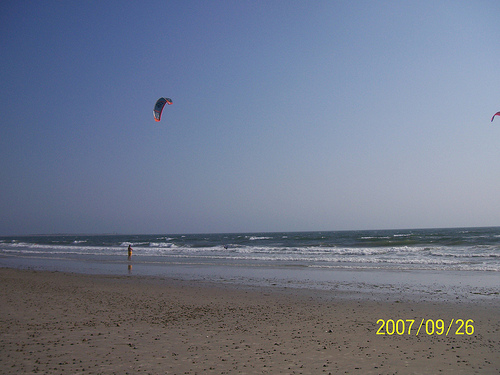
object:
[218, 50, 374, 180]
no clouds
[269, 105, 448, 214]
small tree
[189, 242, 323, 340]
wet sand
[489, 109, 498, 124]
parachute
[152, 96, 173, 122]
kite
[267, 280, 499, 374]
ground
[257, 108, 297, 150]
wall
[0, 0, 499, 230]
blue sky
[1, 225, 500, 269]
ocean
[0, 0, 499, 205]
cloud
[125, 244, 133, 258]
person standing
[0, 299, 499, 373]
footprints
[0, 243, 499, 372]
beach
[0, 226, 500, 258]
wave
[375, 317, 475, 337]
date stamp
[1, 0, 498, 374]
photo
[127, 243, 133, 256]
person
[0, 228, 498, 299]
water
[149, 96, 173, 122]
parachute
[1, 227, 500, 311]
ocean water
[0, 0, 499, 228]
sky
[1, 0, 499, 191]
air